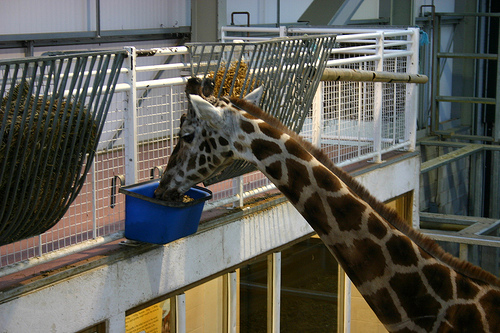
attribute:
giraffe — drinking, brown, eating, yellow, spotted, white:
[153, 73, 499, 333]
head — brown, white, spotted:
[152, 72, 272, 212]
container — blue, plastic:
[114, 175, 212, 246]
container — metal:
[4, 48, 132, 248]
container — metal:
[185, 37, 339, 185]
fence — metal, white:
[2, 26, 429, 285]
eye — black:
[180, 129, 195, 144]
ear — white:
[186, 89, 224, 132]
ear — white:
[237, 81, 266, 110]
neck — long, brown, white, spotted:
[248, 112, 499, 327]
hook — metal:
[109, 171, 124, 212]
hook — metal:
[150, 163, 162, 179]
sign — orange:
[122, 304, 167, 332]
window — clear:
[278, 232, 348, 332]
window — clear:
[235, 248, 277, 332]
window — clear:
[182, 264, 232, 331]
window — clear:
[355, 189, 414, 332]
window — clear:
[124, 293, 174, 332]